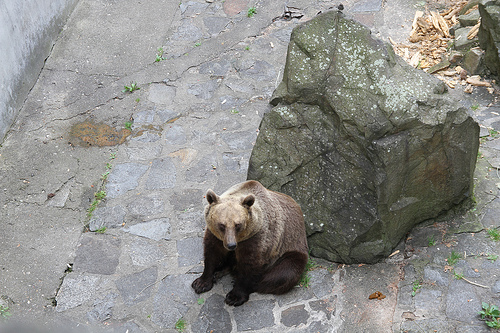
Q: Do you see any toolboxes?
A: No, there are no toolboxes.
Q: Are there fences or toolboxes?
A: No, there are no toolboxes or fences.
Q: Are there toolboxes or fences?
A: No, there are no toolboxes or fences.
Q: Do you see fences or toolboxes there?
A: No, there are no toolboxes or fences.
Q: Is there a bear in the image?
A: Yes, there is a bear.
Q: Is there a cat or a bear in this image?
A: Yes, there is a bear.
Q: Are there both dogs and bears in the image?
A: No, there is a bear but no dogs.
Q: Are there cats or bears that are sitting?
A: Yes, the bear is sitting.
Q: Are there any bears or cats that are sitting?
A: Yes, the bear is sitting.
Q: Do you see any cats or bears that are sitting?
A: Yes, the bear is sitting.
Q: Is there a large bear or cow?
A: Yes, there is a large bear.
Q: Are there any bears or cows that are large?
A: Yes, the bear is large.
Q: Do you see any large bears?
A: Yes, there is a large bear.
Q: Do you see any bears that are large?
A: Yes, there is a bear that is large.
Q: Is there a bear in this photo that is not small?
A: Yes, there is a large bear.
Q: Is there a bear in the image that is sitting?
A: Yes, there is a bear that is sitting.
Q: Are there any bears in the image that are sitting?
A: Yes, there is a bear that is sitting.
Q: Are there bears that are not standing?
A: Yes, there is a bear that is sitting.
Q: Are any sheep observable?
A: No, there are no sheep.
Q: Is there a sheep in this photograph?
A: No, there is no sheep.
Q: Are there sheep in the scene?
A: No, there are no sheep.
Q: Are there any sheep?
A: No, there are no sheep.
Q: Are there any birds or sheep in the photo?
A: No, there are no sheep or birds.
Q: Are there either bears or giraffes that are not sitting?
A: No, there is a bear but it is sitting.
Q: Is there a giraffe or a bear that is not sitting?
A: No, there is a bear but it is sitting.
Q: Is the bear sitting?
A: Yes, the bear is sitting.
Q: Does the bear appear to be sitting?
A: Yes, the bear is sitting.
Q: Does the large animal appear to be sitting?
A: Yes, the bear is sitting.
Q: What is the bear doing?
A: The bear is sitting.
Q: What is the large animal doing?
A: The bear is sitting.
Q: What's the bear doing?
A: The bear is sitting.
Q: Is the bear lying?
A: No, the bear is sitting.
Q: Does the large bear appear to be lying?
A: No, the bear is sitting.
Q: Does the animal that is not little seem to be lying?
A: No, the bear is sitting.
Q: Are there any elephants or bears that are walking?
A: No, there is a bear but it is sitting.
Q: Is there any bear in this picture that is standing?
A: No, there is a bear but it is sitting.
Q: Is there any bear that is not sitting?
A: No, there is a bear but it is sitting.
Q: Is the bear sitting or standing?
A: The bear is sitting.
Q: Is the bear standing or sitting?
A: The bear is sitting.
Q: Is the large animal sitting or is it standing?
A: The bear is sitting.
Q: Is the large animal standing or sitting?
A: The bear is sitting.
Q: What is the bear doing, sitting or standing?
A: The bear is sitting.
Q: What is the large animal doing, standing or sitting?
A: The bear is sitting.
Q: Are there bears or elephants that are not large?
A: No, there is a bear but it is large.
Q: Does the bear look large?
A: Yes, the bear is large.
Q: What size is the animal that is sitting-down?
A: The bear is large.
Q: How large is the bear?
A: The bear is large.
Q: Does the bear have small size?
A: No, the bear is large.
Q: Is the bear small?
A: No, the bear is large.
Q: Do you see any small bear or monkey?
A: No, there is a bear but it is large.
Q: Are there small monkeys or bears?
A: No, there is a bear but it is large.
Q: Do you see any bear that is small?
A: No, there is a bear but it is large.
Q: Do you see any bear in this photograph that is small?
A: No, there is a bear but it is large.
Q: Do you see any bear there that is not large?
A: No, there is a bear but it is large.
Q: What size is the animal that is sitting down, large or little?
A: The bear is large.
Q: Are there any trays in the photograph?
A: No, there are no trays.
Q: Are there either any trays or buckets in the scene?
A: No, there are no trays or buckets.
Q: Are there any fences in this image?
A: No, there are no fences.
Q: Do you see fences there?
A: No, there are no fences.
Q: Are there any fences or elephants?
A: No, there are no fences or elephants.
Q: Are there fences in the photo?
A: No, there are no fences.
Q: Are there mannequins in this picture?
A: No, there are no mannequins.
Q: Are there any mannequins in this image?
A: No, there are no mannequins.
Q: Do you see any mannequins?
A: No, there are no mannequins.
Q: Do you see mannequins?
A: No, there are no mannequins.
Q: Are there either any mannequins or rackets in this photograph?
A: No, there are no mannequins or rackets.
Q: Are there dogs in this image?
A: No, there are no dogs.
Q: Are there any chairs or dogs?
A: No, there are no dogs or chairs.